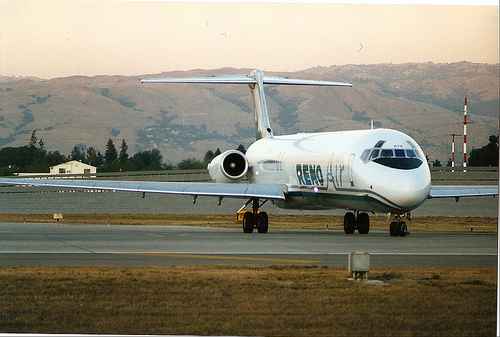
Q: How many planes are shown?
A: One.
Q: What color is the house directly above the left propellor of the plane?
A: White.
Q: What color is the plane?
A: White.